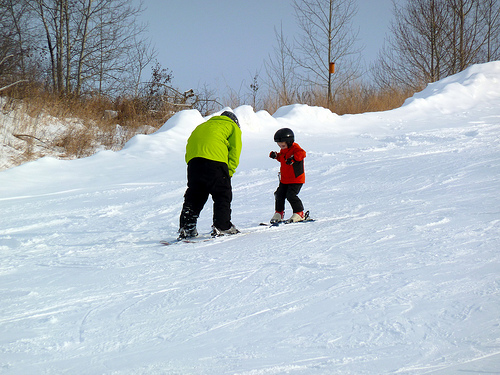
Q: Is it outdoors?
A: Yes, it is outdoors.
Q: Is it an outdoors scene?
A: Yes, it is outdoors.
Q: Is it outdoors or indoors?
A: It is outdoors.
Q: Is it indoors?
A: No, it is outdoors.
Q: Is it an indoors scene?
A: No, it is outdoors.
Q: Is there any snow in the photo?
A: Yes, there is snow.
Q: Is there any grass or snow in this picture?
A: Yes, there is snow.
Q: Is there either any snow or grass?
A: Yes, there is snow.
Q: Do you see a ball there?
A: No, there are no balls.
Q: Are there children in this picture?
A: Yes, there is a child.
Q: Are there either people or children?
A: Yes, there is a child.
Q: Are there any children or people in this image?
A: Yes, there is a child.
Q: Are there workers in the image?
A: No, there are no workers.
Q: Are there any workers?
A: No, there are no workers.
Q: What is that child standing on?
A: The child is standing on the ski.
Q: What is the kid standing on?
A: The kid is standing on the ski.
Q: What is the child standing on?
A: The kid is standing on the ski.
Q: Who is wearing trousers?
A: The child is wearing trousers.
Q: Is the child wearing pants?
A: Yes, the child is wearing pants.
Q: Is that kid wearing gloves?
A: No, the kid is wearing pants.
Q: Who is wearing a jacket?
A: The kid is wearing a jacket.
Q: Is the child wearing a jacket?
A: Yes, the child is wearing a jacket.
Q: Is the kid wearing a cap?
A: No, the kid is wearing a jacket.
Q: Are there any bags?
A: No, there are no bags.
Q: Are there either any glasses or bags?
A: No, there are no bags or glasses.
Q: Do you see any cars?
A: No, there are no cars.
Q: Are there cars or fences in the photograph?
A: No, there are no cars or fences.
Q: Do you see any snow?
A: Yes, there is snow.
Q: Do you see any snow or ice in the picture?
A: Yes, there is snow.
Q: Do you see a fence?
A: No, there are no fences.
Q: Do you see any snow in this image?
A: Yes, there is snow.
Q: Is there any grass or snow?
A: Yes, there is snow.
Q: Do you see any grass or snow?
A: Yes, there is snow.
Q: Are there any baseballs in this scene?
A: No, there are no baseballs.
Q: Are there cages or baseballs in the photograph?
A: No, there are no baseballs or cages.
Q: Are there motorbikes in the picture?
A: No, there are no motorbikes.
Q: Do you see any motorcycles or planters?
A: No, there are no motorcycles or planters.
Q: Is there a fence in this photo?
A: No, there are no fences.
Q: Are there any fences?
A: No, there are no fences.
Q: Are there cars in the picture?
A: No, there are no cars.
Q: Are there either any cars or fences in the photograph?
A: No, there are no cars or fences.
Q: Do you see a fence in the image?
A: No, there are no fences.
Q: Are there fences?
A: No, there are no fences.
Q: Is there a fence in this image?
A: No, there are no fences.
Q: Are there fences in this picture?
A: No, there are no fences.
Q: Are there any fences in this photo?
A: No, there are no fences.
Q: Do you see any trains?
A: No, there are no trains.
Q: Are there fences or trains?
A: No, there are no trains or fences.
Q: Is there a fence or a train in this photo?
A: No, there are no trains or fences.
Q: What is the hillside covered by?
A: The hillside is covered by the snow.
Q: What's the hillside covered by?
A: The hillside is covered by the snow.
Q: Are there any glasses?
A: No, there are no glasses.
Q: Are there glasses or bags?
A: No, there are no glasses or bags.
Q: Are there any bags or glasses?
A: No, there are no glasses or bags.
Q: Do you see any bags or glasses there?
A: No, there are no glasses or bags.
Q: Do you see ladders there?
A: No, there are no ladders.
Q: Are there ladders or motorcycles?
A: No, there are no ladders or motorcycles.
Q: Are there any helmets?
A: Yes, there is a helmet.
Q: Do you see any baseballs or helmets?
A: Yes, there is a helmet.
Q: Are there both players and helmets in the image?
A: No, there is a helmet but no players.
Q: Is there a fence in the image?
A: No, there are no fences.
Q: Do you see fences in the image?
A: No, there are no fences.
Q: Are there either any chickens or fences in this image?
A: No, there are no fences or chickens.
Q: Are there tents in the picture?
A: No, there are no tents.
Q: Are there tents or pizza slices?
A: No, there are no tents or pizza slices.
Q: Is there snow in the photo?
A: Yes, there is snow.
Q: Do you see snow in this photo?
A: Yes, there is snow.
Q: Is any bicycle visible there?
A: No, there are no bicycles.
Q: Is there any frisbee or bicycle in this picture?
A: No, there are no bicycles or frisbees.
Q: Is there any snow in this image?
A: Yes, there is snow.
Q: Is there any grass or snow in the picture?
A: Yes, there is snow.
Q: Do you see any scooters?
A: No, there are no scooters.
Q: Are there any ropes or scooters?
A: No, there are no scooters or ropes.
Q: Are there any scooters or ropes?
A: No, there are no scooters or ropes.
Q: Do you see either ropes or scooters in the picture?
A: No, there are no scooters or ropes.